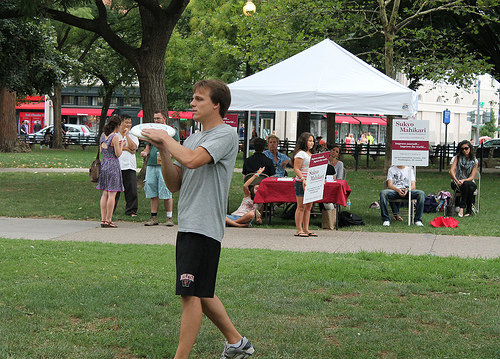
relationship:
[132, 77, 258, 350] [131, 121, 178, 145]
man holding frisbee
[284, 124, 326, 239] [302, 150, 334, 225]
girl holding sign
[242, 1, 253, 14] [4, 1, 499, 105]
light in trees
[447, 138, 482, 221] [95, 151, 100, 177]
woman carrying purse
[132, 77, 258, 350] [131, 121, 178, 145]
man catching frisbee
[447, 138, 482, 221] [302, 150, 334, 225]
woman holding sign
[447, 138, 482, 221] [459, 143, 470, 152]
woman wearing sunglasses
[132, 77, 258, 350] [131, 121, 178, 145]
man playing frisbee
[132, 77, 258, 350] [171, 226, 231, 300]
man wearing shorts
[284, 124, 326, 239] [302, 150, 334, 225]
girl carrying sign